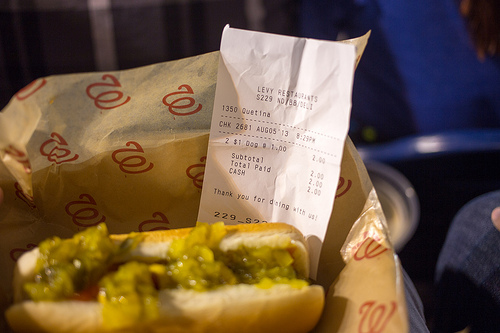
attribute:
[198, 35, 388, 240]
receipt — white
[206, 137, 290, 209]
words — black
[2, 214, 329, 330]
bun — hot dog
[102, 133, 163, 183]
letter — red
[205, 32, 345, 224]
receipt — white, black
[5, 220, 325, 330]
hot dog — purchased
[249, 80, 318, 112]
writing — English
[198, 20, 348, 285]
purchase — Levy Restaurant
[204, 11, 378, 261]
receipt — dinner, restaurant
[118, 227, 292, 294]
relish — green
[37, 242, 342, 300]
hotdog — brown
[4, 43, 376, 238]
paper — brown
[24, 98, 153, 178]
liner — paper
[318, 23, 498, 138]
shirt — blue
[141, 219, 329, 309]
mustard — yellow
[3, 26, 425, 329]
package — tan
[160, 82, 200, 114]
letter — red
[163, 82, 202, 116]
logo — W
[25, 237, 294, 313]
inside — white